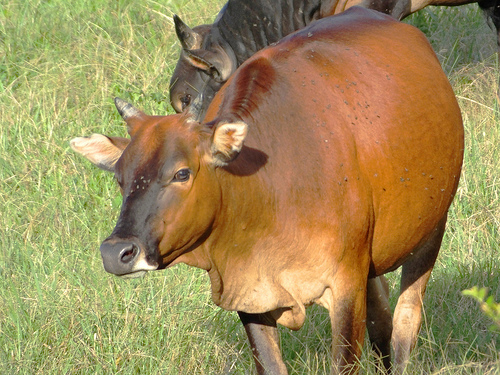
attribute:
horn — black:
[180, 91, 215, 126]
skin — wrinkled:
[243, 4, 323, 33]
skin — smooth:
[72, 8, 464, 371]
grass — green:
[3, 4, 498, 363]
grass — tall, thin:
[289, 317, 498, 373]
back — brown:
[258, 18, 387, 108]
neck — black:
[218, 4, 285, 30]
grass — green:
[30, 221, 84, 317]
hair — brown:
[224, 126, 233, 168]